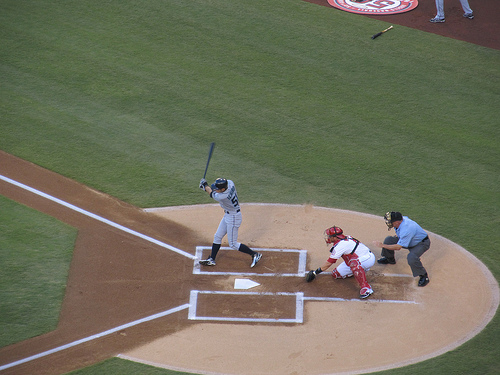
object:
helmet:
[209, 176, 227, 189]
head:
[210, 175, 230, 194]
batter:
[196, 175, 263, 269]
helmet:
[321, 224, 347, 245]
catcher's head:
[320, 225, 346, 243]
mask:
[322, 230, 332, 248]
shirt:
[208, 178, 242, 214]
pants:
[211, 211, 245, 254]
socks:
[235, 241, 259, 258]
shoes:
[247, 252, 263, 269]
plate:
[231, 277, 262, 291]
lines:
[195, 269, 305, 278]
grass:
[0, 194, 78, 348]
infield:
[0, 149, 196, 375]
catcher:
[300, 225, 378, 302]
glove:
[301, 268, 321, 284]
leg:
[223, 216, 255, 258]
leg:
[209, 216, 233, 261]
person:
[371, 209, 432, 289]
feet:
[414, 275, 432, 288]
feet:
[355, 283, 374, 301]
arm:
[200, 184, 234, 204]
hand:
[197, 178, 210, 189]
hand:
[373, 240, 382, 250]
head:
[381, 208, 404, 229]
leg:
[405, 238, 426, 280]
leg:
[380, 235, 403, 260]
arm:
[380, 228, 411, 252]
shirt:
[391, 216, 429, 250]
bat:
[201, 137, 218, 182]